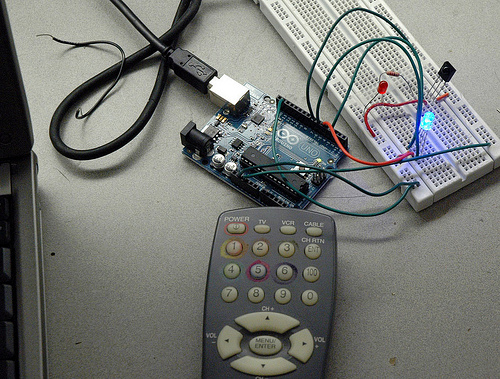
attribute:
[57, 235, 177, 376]
floor — grey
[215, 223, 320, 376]
keyboard — grey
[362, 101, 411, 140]
cable — red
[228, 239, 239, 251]
number — black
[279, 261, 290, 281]
number — black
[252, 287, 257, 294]
number — black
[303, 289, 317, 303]
number — black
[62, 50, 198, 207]
cord — long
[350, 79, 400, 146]
wire — red